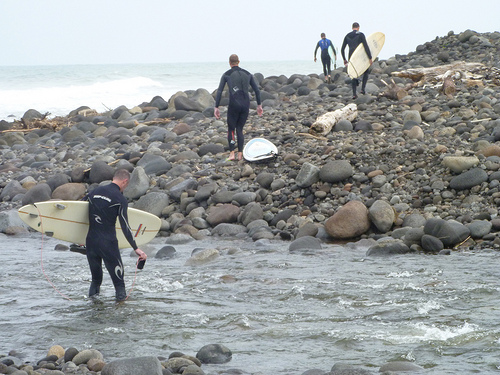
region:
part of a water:
[246, 255, 280, 292]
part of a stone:
[334, 199, 376, 241]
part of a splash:
[283, 292, 317, 325]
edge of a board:
[131, 202, 153, 227]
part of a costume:
[96, 237, 120, 282]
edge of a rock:
[207, 347, 227, 357]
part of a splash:
[213, 272, 264, 327]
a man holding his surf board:
[16, 169, 176, 323]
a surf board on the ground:
[240, 131, 283, 176]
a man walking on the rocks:
[203, 47, 268, 164]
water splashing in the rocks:
[239, 258, 488, 360]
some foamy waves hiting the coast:
[0, 66, 178, 138]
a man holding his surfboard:
[341, 18, 405, 98]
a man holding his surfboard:
[312, 24, 342, 93]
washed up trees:
[387, 61, 487, 104]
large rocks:
[285, 168, 496, 258]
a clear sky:
[32, 8, 236, 47]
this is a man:
[218, 47, 253, 129]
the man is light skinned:
[116, 176, 132, 190]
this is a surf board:
[252, 133, 270, 164]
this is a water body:
[241, 283, 343, 339]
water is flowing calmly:
[299, 283, 389, 335]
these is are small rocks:
[358, 168, 448, 200]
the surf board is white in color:
[54, 214, 79, 230]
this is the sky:
[33, 12, 237, 50]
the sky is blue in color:
[15, 22, 69, 39]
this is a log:
[310, 110, 340, 127]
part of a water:
[242, 249, 279, 304]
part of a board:
[133, 214, 160, 240]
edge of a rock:
[327, 205, 351, 227]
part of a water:
[264, 325, 299, 360]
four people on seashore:
[85, 18, 383, 308]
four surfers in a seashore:
[86, 20, 367, 301]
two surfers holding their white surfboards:
[82, 15, 372, 301]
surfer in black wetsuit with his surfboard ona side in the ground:
[210, 55, 255, 156]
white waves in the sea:
[0, 71, 180, 126]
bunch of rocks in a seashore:
[0, 30, 495, 235]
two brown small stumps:
[312, 56, 487, 126]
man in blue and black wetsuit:
[310, 30, 335, 75]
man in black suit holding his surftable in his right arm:
[340, 20, 370, 96]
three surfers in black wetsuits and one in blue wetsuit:
[81, 20, 371, 300]